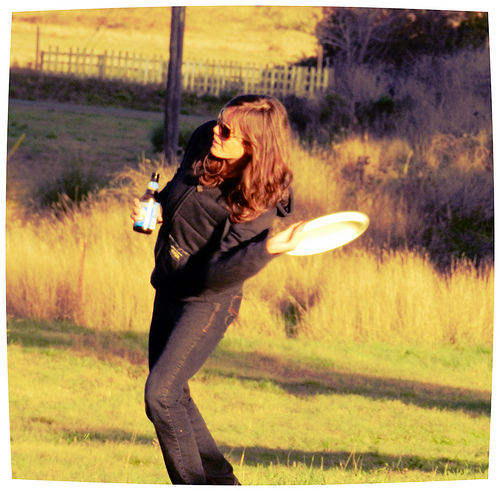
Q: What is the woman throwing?
A: Frisbee.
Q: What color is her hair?
A: Brown.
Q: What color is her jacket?
A: Black.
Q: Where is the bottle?
A: Right Hand.